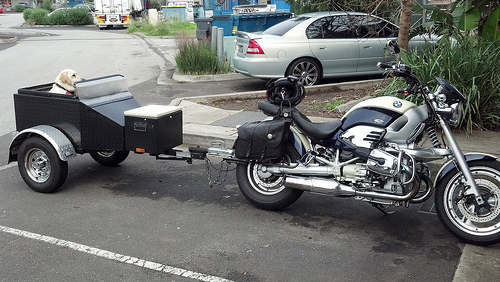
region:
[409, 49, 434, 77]
tall grass on ground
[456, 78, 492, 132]
tall grass on ground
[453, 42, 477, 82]
tall grass on ground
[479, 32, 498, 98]
tall grass on ground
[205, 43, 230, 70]
tall grass on ground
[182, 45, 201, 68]
tall grass on ground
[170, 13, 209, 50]
tall grass on ground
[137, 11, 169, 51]
tall grass on ground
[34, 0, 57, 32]
tall grass on ground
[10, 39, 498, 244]
a motorcycle pulling a trailer with a dog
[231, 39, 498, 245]
a silver and black motorcycle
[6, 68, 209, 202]
a small black trailer with a dog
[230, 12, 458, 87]
a silver car in the driveway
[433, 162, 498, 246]
the front wheel on the motorcycle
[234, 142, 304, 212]
the rear wheel on the motorcycle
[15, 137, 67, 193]
the rear wheel on the trailer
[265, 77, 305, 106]
a motorcycle helmet on the seat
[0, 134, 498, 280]
the grey asphalt parking lot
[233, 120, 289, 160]
a black bag on back of motorcycle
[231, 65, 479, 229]
motorcycle parked on street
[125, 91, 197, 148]
cooler on back of atachment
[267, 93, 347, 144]
black seat on motorcycle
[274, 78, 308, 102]
black helmet on motorcycle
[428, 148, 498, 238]
front wheel of motorcycle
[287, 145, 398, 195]
silver engine on motorcycle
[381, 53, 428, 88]
handle bars on front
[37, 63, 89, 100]
white dog sitting down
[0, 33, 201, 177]
back attachment of motorcycle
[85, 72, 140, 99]
back window of attachment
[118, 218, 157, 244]
Small patch of the black street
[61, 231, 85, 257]
Solid white line on the street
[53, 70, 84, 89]
Dog sitting in the cart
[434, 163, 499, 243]
Front wheel on the motorcycle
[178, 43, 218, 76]
Patch of a green bush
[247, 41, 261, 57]
Back headlights on the car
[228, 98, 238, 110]
Small patch of dirt on the ground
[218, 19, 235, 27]
Small blue part of the dumpster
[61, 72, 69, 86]
Right brown ear of the dog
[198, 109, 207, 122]
Small part of the sidewalk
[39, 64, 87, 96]
a yellow lab with a black collar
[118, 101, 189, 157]
a black metal compartment for storage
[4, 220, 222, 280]
white line painted on the road to mark parking spots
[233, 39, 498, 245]
a black and white bmw motorcycle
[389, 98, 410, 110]
the BMW emblem on the gas tank over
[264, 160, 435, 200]
exhaust pipes on the motorcycle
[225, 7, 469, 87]
grey two door car going down an alley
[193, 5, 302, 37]
blue trash dumpster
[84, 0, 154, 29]
the back end of a tractor trailor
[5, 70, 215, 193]
a pull cart with a dog inside